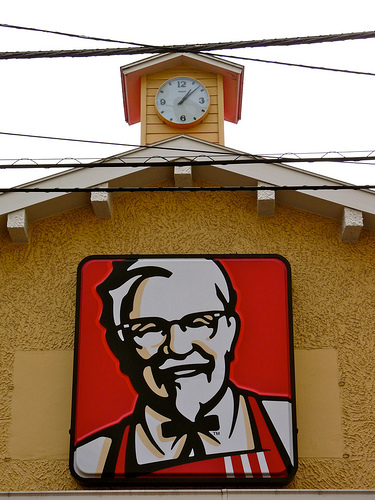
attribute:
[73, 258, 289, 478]
person — comic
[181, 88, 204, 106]
hands —  black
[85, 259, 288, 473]
frame — red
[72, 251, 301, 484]
sign — large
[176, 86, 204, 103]
hands — black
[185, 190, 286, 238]
wall — brown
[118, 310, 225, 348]
glasses — black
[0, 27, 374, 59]
rope — wooden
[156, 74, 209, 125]
clock — white, black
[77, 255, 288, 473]
picture — sketchy